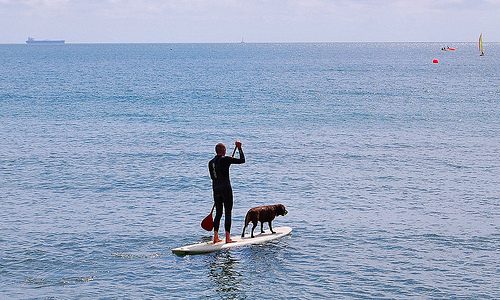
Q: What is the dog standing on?
A: A surf board.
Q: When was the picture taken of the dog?
A: Daytime.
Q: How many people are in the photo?
A: One.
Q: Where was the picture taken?
A: The beach.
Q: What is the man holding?
A: A paddle.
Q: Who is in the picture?
A: A man.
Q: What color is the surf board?
A: White.